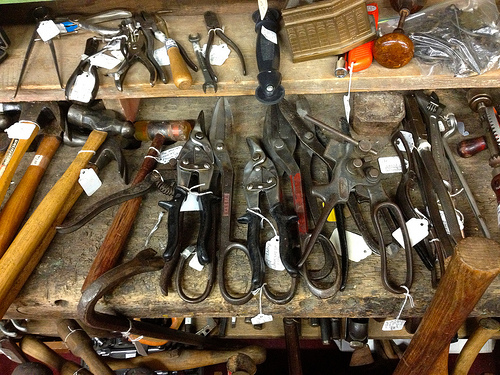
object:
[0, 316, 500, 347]
shelf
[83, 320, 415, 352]
edge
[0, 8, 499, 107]
shelf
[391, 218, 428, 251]
tag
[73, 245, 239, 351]
crowbar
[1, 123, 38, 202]
handle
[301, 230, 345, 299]
handle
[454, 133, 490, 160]
tools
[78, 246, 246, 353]
pry bar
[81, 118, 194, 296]
hammer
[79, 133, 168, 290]
mallet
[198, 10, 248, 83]
pliers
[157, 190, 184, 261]
handle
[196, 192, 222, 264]
handle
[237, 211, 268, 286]
handle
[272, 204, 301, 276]
handle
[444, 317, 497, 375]
tools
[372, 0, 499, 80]
bag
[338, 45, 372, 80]
tools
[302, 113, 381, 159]
tools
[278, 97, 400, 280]
tools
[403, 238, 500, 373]
handle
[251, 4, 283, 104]
handle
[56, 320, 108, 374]
handle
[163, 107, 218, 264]
tool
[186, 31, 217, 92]
tool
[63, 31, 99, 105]
tool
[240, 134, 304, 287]
tool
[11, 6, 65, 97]
tool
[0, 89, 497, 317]
board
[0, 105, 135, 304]
hammer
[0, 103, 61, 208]
hammer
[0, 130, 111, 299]
handle